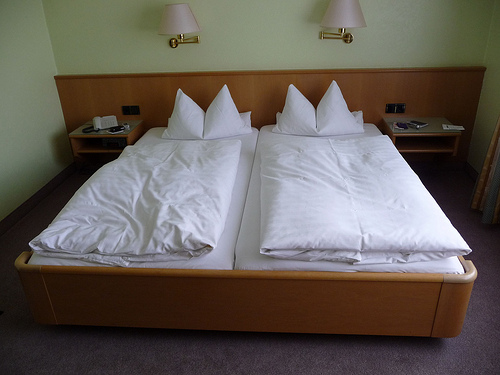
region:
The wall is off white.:
[221, 8, 301, 63]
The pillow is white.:
[271, 79, 367, 135]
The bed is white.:
[273, 148, 388, 231]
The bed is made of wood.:
[235, 280, 399, 331]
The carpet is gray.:
[20, 333, 120, 373]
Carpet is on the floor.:
[12, 336, 119, 373]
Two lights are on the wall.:
[142, 0, 374, 50]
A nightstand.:
[378, 98, 465, 178]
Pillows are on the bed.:
[154, 78, 370, 149]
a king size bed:
[32, 53, 494, 335]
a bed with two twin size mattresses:
[67, 39, 479, 355]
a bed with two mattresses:
[104, 65, 419, 372]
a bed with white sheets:
[55, 21, 492, 357]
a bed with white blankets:
[72, 65, 483, 374]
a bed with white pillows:
[68, 43, 493, 353]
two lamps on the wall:
[132, 1, 415, 68]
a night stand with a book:
[17, 34, 285, 239]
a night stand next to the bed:
[35, 61, 303, 218]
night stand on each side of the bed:
[51, 58, 486, 258]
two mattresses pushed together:
[20, 80, 485, 352]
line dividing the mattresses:
[223, 123, 263, 270]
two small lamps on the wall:
[148, 4, 393, 56]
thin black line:
[422, 278, 447, 342]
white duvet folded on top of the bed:
[243, 128, 465, 277]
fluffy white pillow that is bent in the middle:
[153, 79, 256, 142]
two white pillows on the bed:
[158, 81, 395, 152]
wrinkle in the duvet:
[85, 175, 149, 242]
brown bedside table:
[377, 104, 468, 189]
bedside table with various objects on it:
[50, 106, 145, 177]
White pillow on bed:
[277, 79, 364, 138]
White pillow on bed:
[165, 82, 255, 137]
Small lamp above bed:
[148, 2, 203, 49]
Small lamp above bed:
[317, 0, 369, 46]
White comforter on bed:
[254, 138, 475, 261]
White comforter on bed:
[27, 141, 243, 265]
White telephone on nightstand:
[89, 108, 120, 131]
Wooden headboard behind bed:
[52, 63, 484, 155]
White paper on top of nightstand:
[439, 120, 469, 133]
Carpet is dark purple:
[0, 173, 499, 373]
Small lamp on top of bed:
[160, 1, 200, 52]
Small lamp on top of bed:
[312, 0, 369, 48]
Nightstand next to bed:
[384, 110, 465, 169]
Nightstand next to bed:
[63, 118, 143, 154]